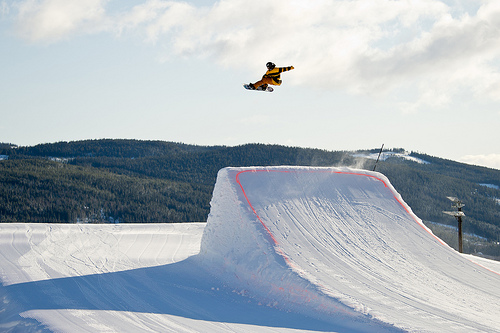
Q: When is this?
A: Daytime.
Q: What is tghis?
A: A snowhill.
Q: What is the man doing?
A: Skating.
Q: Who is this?
A: A man.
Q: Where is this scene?
A: A ski slope.